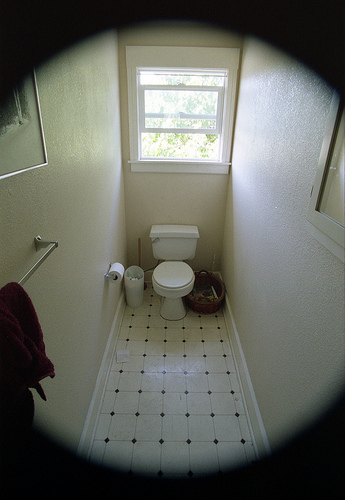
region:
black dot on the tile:
[227, 388, 236, 396]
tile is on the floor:
[172, 396, 186, 415]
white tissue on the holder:
[115, 265, 123, 273]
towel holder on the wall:
[39, 239, 58, 249]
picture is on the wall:
[15, 110, 37, 156]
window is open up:
[156, 141, 185, 150]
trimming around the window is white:
[159, 164, 189, 173]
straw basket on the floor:
[199, 299, 218, 306]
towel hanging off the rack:
[12, 335, 40, 367]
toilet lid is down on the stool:
[163, 272, 183, 289]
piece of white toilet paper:
[116, 347, 130, 365]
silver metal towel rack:
[17, 233, 60, 287]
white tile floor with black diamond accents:
[90, 281, 258, 481]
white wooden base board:
[77, 268, 275, 459]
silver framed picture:
[0, 65, 48, 179]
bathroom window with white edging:
[126, 46, 240, 174]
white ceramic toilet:
[148, 225, 200, 321]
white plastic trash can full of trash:
[124, 264, 143, 308]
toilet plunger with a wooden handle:
[135, 234, 147, 290]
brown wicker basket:
[183, 266, 226, 313]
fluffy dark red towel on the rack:
[1, 281, 54, 422]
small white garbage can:
[123, 264, 142, 307]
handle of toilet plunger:
[136, 237, 141, 266]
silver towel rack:
[3, 232, 59, 290]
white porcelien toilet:
[149, 223, 199, 318]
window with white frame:
[124, 43, 240, 177]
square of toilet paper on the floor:
[115, 347, 129, 361]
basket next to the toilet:
[190, 268, 225, 311]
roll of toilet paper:
[108, 260, 125, 280]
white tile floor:
[91, 280, 257, 474]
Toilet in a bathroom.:
[107, 220, 189, 319]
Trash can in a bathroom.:
[123, 264, 147, 306]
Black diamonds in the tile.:
[100, 429, 113, 450]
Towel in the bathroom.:
[0, 275, 65, 421]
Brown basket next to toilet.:
[197, 265, 227, 313]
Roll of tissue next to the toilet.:
[104, 263, 124, 283]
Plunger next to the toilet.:
[131, 233, 150, 296]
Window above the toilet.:
[121, 39, 241, 177]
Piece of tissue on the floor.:
[113, 346, 134, 365]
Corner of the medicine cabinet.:
[297, 100, 337, 226]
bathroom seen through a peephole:
[11, 36, 325, 485]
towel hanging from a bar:
[0, 270, 54, 433]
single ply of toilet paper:
[113, 345, 129, 360]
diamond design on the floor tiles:
[153, 432, 162, 442]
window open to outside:
[121, 63, 230, 171]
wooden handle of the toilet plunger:
[131, 233, 139, 260]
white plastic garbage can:
[122, 261, 144, 303]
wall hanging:
[0, 39, 48, 183]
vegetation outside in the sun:
[141, 130, 214, 153]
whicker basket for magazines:
[188, 263, 224, 312]